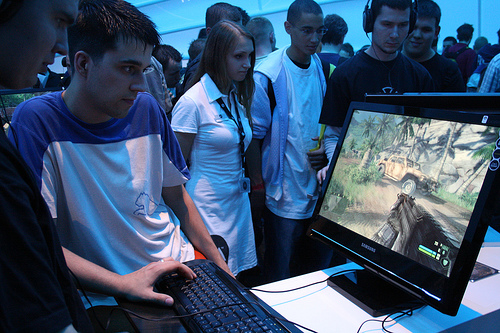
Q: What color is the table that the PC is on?
A: White.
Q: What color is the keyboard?
A: Black.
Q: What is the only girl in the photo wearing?
A: White dress.